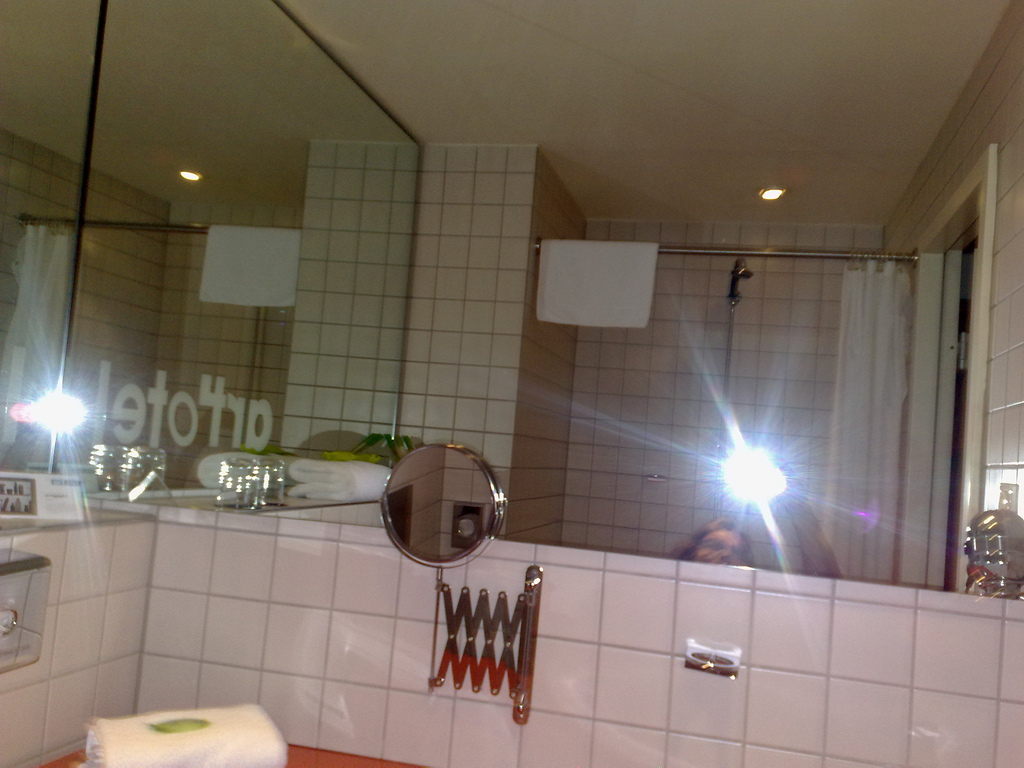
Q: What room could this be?
A: It is a bathroom.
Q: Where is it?
A: This is at the bathroom.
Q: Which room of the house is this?
A: It is a bathroom.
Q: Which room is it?
A: It is a bathroom.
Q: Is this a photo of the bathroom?
A: Yes, it is showing the bathroom.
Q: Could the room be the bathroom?
A: Yes, it is the bathroom.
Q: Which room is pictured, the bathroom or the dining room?
A: It is the bathroom.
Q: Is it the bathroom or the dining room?
A: It is the bathroom.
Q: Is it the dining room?
A: No, it is the bathroom.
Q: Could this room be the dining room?
A: No, it is the bathroom.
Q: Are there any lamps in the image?
A: No, there are no lamps.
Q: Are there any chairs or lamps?
A: No, there are no lamps or chairs.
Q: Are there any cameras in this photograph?
A: Yes, there is a camera.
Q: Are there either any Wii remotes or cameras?
A: Yes, there is a camera.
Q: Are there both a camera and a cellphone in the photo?
A: No, there is a camera but no cell phones.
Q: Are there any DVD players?
A: No, there are no DVD players.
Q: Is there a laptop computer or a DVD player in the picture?
A: No, there are no DVD players or laptops.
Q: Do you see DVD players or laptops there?
A: No, there are no DVD players or laptops.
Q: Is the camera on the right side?
A: Yes, the camera is on the right of the image.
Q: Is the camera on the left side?
A: No, the camera is on the right of the image.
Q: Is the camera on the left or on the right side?
A: The camera is on the right of the image.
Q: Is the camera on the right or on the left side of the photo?
A: The camera is on the right of the image.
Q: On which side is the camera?
A: The camera is on the right of the image.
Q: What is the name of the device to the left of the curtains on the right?
A: The device is a camera.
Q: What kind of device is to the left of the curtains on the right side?
A: The device is a camera.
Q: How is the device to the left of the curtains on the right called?
A: The device is a camera.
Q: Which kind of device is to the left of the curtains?
A: The device is a camera.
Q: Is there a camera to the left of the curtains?
A: Yes, there is a camera to the left of the curtains.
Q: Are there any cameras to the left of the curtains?
A: Yes, there is a camera to the left of the curtains.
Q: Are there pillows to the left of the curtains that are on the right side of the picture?
A: No, there is a camera to the left of the curtains.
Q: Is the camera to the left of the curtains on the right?
A: Yes, the camera is to the left of the curtains.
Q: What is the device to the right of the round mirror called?
A: The device is a camera.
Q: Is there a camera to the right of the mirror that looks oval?
A: Yes, there is a camera to the right of the mirror.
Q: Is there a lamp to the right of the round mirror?
A: No, there is a camera to the right of the mirror.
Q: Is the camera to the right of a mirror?
A: Yes, the camera is to the right of a mirror.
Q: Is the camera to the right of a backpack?
A: No, the camera is to the right of a mirror.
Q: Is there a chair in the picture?
A: No, there are no chairs.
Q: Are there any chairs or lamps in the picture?
A: No, there are no chairs or lamps.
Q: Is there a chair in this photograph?
A: No, there are no chairs.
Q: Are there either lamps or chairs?
A: No, there are no chairs or lamps.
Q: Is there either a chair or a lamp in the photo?
A: No, there are no chairs or lamps.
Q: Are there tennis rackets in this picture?
A: No, there are no tennis rackets.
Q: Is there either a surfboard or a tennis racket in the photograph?
A: No, there are no rackets or surfboards.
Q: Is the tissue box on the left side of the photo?
A: Yes, the tissue box is on the left of the image.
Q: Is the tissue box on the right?
A: No, the tissue box is on the left of the image.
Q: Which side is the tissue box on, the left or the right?
A: The tissue box is on the left of the image.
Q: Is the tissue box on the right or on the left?
A: The tissue box is on the left of the image.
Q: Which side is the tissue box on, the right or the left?
A: The tissue box is on the left of the image.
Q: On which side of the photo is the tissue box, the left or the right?
A: The tissue box is on the left of the image.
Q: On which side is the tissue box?
A: The tissue box is on the left of the image.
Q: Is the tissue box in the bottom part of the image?
A: Yes, the tissue box is in the bottom of the image.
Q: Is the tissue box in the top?
A: No, the tissue box is in the bottom of the image.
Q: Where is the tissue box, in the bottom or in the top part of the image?
A: The tissue box is in the bottom of the image.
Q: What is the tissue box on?
A: The tissue box is on the wall.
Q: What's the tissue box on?
A: The tissue box is on the wall.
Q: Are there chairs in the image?
A: No, there are no chairs.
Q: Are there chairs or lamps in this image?
A: No, there are no chairs or lamps.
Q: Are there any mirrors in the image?
A: Yes, there is a mirror.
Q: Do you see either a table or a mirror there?
A: Yes, there is a mirror.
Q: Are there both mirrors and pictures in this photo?
A: Yes, there are both a mirror and a picture.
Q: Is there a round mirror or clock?
A: Yes, there is a round mirror.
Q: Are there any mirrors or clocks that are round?
A: Yes, the mirror is round.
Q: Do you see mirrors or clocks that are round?
A: Yes, the mirror is round.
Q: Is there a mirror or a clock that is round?
A: Yes, the mirror is round.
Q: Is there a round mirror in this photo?
A: Yes, there is a round mirror.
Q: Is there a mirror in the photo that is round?
A: Yes, there is a mirror that is round.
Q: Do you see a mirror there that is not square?
A: Yes, there is a round mirror.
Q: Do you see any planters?
A: No, there are no planters.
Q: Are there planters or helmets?
A: No, there are no planters or helmets.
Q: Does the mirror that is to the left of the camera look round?
A: Yes, the mirror is round.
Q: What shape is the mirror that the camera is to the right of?
A: The mirror is round.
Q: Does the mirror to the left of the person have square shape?
A: No, the mirror is round.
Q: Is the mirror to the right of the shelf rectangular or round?
A: The mirror is round.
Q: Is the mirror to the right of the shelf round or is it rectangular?
A: The mirror is round.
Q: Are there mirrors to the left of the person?
A: Yes, there is a mirror to the left of the person.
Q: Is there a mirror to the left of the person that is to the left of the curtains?
A: Yes, there is a mirror to the left of the person.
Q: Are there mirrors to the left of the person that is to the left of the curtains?
A: Yes, there is a mirror to the left of the person.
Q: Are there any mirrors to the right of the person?
A: No, the mirror is to the left of the person.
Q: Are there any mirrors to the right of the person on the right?
A: No, the mirror is to the left of the person.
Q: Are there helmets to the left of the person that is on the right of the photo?
A: No, there is a mirror to the left of the person.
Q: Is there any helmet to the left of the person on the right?
A: No, there is a mirror to the left of the person.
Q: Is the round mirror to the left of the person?
A: Yes, the mirror is to the left of the person.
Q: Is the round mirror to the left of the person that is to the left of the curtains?
A: Yes, the mirror is to the left of the person.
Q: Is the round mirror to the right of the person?
A: No, the mirror is to the left of the person.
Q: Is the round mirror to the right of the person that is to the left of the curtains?
A: No, the mirror is to the left of the person.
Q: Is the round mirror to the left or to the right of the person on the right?
A: The mirror is to the left of the person.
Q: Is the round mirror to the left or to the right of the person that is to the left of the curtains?
A: The mirror is to the left of the person.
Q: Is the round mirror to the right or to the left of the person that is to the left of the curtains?
A: The mirror is to the left of the person.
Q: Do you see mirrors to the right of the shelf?
A: Yes, there is a mirror to the right of the shelf.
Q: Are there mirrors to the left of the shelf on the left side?
A: No, the mirror is to the right of the shelf.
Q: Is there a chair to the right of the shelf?
A: No, there is a mirror to the right of the shelf.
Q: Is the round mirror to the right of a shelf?
A: Yes, the mirror is to the right of a shelf.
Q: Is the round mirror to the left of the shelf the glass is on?
A: No, the mirror is to the right of the shelf.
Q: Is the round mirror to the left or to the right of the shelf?
A: The mirror is to the right of the shelf.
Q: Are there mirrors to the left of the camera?
A: Yes, there is a mirror to the left of the camera.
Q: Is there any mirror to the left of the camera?
A: Yes, there is a mirror to the left of the camera.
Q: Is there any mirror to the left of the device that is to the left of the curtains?
A: Yes, there is a mirror to the left of the camera.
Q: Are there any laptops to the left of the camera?
A: No, there is a mirror to the left of the camera.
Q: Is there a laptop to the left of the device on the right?
A: No, there is a mirror to the left of the camera.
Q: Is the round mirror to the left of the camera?
A: Yes, the mirror is to the left of the camera.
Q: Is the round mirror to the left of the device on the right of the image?
A: Yes, the mirror is to the left of the camera.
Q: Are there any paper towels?
A: No, there are no paper towels.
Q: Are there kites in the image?
A: No, there are no kites.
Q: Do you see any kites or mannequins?
A: No, there are no kites or mannequins.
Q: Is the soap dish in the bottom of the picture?
A: Yes, the soap dish is in the bottom of the image.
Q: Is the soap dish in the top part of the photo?
A: No, the soap dish is in the bottom of the image.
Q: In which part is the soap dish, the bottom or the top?
A: The soap dish is in the bottom of the image.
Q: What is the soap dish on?
A: The soap dish is on the wall.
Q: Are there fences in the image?
A: No, there are no fences.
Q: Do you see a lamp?
A: No, there are no lamps.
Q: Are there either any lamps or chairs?
A: No, there are no lamps or chairs.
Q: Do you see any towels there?
A: Yes, there is a towel.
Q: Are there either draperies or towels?
A: Yes, there is a towel.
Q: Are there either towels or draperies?
A: Yes, there is a towel.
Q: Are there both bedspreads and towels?
A: No, there is a towel but no bedspreads.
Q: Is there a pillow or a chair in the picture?
A: No, there are no chairs or pillows.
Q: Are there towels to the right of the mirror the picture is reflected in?
A: Yes, there is a towel to the right of the mirror.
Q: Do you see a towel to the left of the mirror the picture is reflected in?
A: No, the towel is to the right of the mirror.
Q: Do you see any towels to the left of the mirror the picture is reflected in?
A: No, the towel is to the right of the mirror.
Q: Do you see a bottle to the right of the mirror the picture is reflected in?
A: No, there is a towel to the right of the mirror.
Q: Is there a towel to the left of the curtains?
A: Yes, there is a towel to the left of the curtains.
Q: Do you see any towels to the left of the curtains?
A: Yes, there is a towel to the left of the curtains.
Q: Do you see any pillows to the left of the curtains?
A: No, there is a towel to the left of the curtains.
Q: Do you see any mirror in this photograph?
A: Yes, there is a mirror.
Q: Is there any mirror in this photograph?
A: Yes, there is a mirror.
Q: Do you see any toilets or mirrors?
A: Yes, there is a mirror.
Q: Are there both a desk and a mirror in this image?
A: No, there is a mirror but no desks.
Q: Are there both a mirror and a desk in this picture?
A: No, there is a mirror but no desks.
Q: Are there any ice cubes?
A: No, there are no ice cubes.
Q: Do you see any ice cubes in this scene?
A: No, there are no ice cubes.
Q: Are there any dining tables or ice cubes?
A: No, there are no ice cubes or dining tables.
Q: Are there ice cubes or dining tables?
A: No, there are no ice cubes or dining tables.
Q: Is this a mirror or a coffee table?
A: This is a mirror.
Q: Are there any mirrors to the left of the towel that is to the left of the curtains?
A: Yes, there is a mirror to the left of the towel.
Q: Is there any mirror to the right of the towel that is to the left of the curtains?
A: No, the mirror is to the left of the towel.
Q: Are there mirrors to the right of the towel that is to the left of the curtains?
A: No, the mirror is to the left of the towel.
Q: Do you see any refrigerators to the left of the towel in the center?
A: No, there is a mirror to the left of the towel.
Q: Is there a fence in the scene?
A: No, there are no fences.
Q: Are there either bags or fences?
A: No, there are no fences or bags.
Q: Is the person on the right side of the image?
A: Yes, the person is on the right of the image.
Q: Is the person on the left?
A: No, the person is on the right of the image.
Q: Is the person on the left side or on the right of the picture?
A: The person is on the right of the image.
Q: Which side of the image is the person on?
A: The person is on the right of the image.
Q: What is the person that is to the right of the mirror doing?
A: The person is taking a picture.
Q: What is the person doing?
A: The person is taking a picture.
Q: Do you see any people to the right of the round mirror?
A: Yes, there is a person to the right of the mirror.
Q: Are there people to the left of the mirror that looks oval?
A: No, the person is to the right of the mirror.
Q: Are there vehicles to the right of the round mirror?
A: No, there is a person to the right of the mirror.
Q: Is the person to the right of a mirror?
A: Yes, the person is to the right of a mirror.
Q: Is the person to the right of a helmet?
A: No, the person is to the right of a mirror.